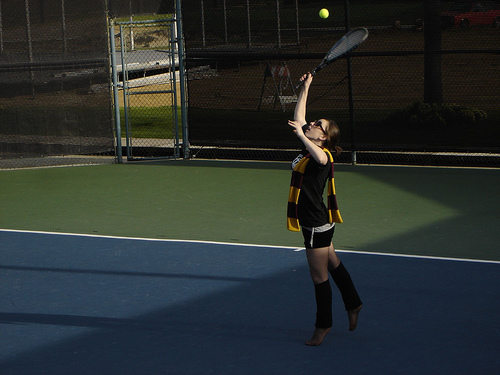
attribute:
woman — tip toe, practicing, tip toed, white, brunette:
[286, 72, 362, 347]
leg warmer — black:
[315, 278, 331, 329]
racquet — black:
[294, 25, 370, 89]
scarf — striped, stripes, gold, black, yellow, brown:
[285, 148, 343, 233]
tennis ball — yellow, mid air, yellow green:
[317, 6, 329, 20]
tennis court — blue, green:
[0, 158, 500, 374]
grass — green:
[1, 103, 497, 155]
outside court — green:
[2, 163, 497, 264]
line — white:
[0, 227, 500, 265]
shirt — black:
[290, 123, 333, 230]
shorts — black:
[299, 221, 335, 249]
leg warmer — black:
[328, 263, 362, 313]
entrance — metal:
[112, 17, 182, 163]